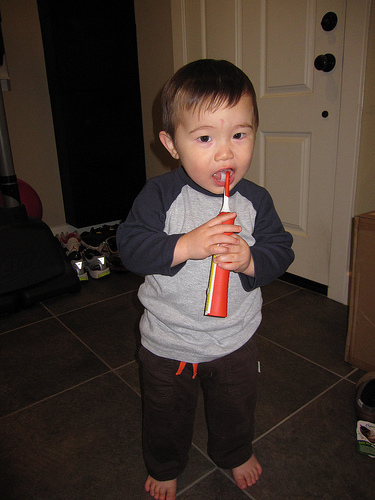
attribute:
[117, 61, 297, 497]
toddler — small, young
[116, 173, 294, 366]
shirt — grey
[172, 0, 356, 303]
door — white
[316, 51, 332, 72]
knob — black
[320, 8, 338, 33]
lock — black, deadbolt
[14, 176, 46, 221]
ball — orange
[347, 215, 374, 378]
box — small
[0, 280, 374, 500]
floor — tile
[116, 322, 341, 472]
tile — grey, dark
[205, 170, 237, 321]
toothbrush — electric, white, orange, long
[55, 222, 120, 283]
shoes — tennis shoes, glow in the dark, green, red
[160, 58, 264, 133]
hair — brown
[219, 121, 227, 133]
scar — red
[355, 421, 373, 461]
magazine — green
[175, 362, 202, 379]
strings — orange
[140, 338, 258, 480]
pants — brown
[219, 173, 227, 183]
bristles — white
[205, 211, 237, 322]
handle — yellow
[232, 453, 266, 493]
foot — bare